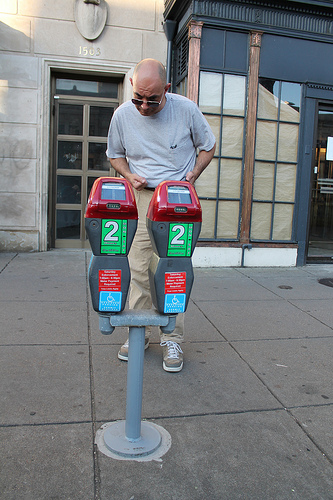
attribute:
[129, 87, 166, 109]
glasses — dark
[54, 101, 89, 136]
pane — glass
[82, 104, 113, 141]
pane — glass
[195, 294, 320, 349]
tiles — paved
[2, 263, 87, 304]
cement square — grey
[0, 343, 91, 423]
cement square — grey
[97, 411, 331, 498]
cement square — grey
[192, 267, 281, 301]
cement square — grey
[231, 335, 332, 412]
cement square — grey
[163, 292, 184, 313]
sign — handicap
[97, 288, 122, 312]
sign — handicap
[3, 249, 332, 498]
pavement — stone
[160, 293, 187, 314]
handicapped label — light blue